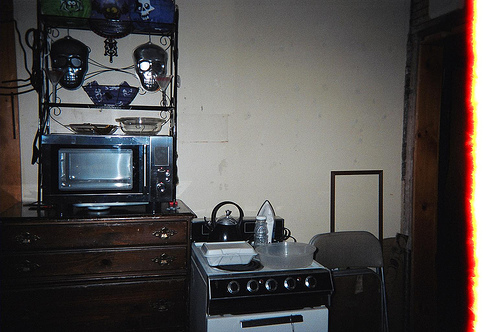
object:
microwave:
[40, 134, 177, 214]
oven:
[188, 213, 335, 331]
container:
[253, 241, 316, 271]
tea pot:
[201, 199, 245, 242]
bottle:
[251, 215, 268, 245]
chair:
[304, 230, 390, 331]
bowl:
[80, 80, 140, 108]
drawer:
[0, 220, 185, 251]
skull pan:
[131, 41, 169, 93]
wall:
[13, 1, 408, 244]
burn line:
[463, 0, 500, 332]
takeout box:
[198, 239, 257, 268]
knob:
[157, 182, 168, 195]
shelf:
[45, 202, 174, 206]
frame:
[330, 167, 383, 246]